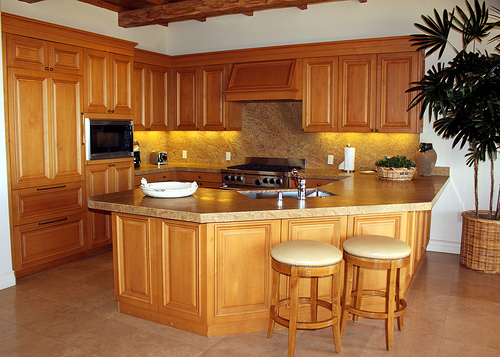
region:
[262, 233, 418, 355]
two bar stools at the kitchen counter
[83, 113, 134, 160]
a stainless steel microwave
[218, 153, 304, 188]
a stainless steel oven and range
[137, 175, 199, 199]
a white bowl on the kitchen counter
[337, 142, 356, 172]
a roll of paper towel on the counter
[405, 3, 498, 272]
a potted plant on the kitchen floor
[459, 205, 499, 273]
a brown wicker styled pot for the plant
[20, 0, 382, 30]
exposed wood beams on the ceiling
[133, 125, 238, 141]
lighting coming from below the cabinets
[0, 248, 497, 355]
a tiled kitchen floor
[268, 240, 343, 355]
a light colored wooden bar stool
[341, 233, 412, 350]
a light colored wooden bar stool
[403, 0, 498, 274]
green potted plant in wicker basket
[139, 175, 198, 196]
a white dish on the counter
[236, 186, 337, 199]
stainless steel kitchen sink on counter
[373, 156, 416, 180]
wicker basket of greenery on counter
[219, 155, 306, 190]
stainless steel oven with range top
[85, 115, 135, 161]
built in microwave oven in wall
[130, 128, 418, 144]
recessed lighting under cabinets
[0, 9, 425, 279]
light colored wooden kitchen cabinets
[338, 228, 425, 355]
Stool near the counter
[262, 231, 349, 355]
Stool near the counter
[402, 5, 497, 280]
Plant against the wall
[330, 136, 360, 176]
Paper towels on the counter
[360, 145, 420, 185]
Plants in wicker basket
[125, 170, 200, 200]
Platter on the counter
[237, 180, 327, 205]
Sink in the counter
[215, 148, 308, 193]
Stove against the wall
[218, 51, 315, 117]
Hood over the stove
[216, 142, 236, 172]
Socket on the wall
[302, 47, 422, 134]
finished wood cabinets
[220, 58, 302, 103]
range hood is blended with cabinets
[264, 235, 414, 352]
two finished bar stools white upholstery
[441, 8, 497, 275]
decorative tropical plant , left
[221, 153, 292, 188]
modern silver cooktop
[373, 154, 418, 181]
basket with plants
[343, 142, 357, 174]
paper towel holder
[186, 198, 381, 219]
sleek granite counter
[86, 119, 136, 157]
built in microwave oven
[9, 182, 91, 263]
blended wood storage drawers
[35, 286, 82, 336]
the floor is tan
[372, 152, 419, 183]
the plant is on the counter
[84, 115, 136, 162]
the microwave is stainless steel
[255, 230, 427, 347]
the stools are short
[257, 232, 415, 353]
the stools have white cushions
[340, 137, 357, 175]
the paper towels are on the counter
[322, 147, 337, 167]
the socket is on the wall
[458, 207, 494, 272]
the basket is wicker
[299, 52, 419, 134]
the cabinettes are brown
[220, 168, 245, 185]
the oven has knobs